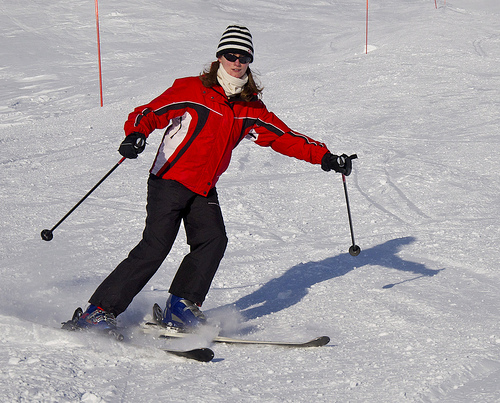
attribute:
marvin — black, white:
[216, 27, 261, 67]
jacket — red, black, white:
[120, 60, 331, 198]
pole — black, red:
[43, 154, 145, 251]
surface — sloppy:
[339, 61, 474, 188]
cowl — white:
[215, 60, 251, 98]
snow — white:
[2, 2, 498, 401]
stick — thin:
[333, 182, 361, 232]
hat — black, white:
[208, 17, 262, 61]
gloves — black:
[319, 150, 352, 175]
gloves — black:
[117, 130, 146, 160]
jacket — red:
[124, 68, 349, 198]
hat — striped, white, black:
[216, 23, 256, 62]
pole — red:
[90, 0, 107, 107]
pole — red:
[362, 2, 371, 53]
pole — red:
[430, 1, 440, 13]